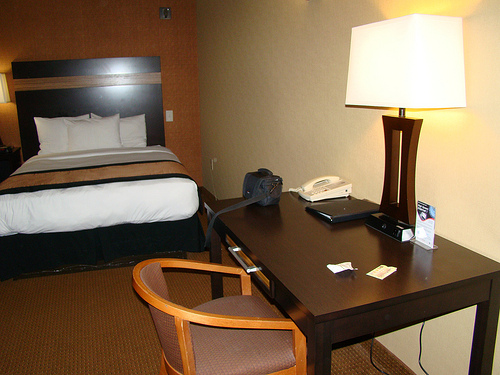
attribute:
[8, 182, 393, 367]
carpet — flat, brown pattern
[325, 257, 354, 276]
paper — piece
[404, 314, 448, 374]
cord — black, hanging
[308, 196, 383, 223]
folder — black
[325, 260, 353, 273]
paper — small piece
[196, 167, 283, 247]
case — black video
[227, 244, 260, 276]
handle — silver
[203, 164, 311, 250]
cord — black, hanging down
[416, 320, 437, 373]
cord — electrical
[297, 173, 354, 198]
phone — white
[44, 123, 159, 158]
pillows — white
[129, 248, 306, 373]
wooden chair — rounded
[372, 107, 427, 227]
base — wooden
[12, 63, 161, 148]
head board — large, wooden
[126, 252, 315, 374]
chair — mismatched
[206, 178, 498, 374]
table — brown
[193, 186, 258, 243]
handle — black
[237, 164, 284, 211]
camera bag — black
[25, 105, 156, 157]
pillow — white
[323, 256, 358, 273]
paper — small